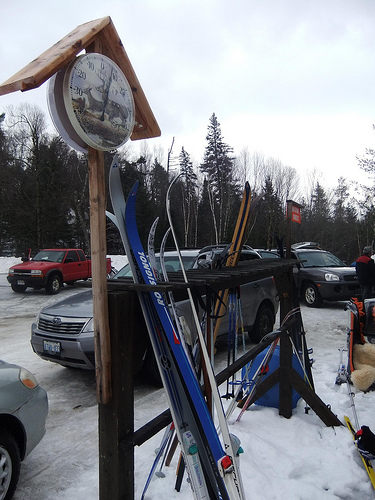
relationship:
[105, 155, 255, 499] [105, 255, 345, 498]
skis in a rack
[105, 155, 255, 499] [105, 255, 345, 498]
skis on rack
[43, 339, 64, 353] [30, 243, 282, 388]
license plate on car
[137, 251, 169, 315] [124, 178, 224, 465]
logo on ski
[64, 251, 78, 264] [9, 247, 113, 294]
window on car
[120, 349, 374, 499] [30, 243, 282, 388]
snow near car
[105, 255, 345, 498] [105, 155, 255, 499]
rack with skis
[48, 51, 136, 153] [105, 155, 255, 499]
clock near skis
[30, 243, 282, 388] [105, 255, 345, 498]
car on street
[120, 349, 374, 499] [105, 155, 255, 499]
snow near skis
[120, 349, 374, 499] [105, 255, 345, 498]
snow on ground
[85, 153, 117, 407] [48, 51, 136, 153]
post with clock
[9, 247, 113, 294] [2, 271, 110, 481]
car on street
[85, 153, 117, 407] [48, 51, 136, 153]
post holding clock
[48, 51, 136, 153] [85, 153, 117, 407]
clock on post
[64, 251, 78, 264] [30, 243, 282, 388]
window on car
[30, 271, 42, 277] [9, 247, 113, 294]
light on car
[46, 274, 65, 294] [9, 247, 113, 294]
tire on car